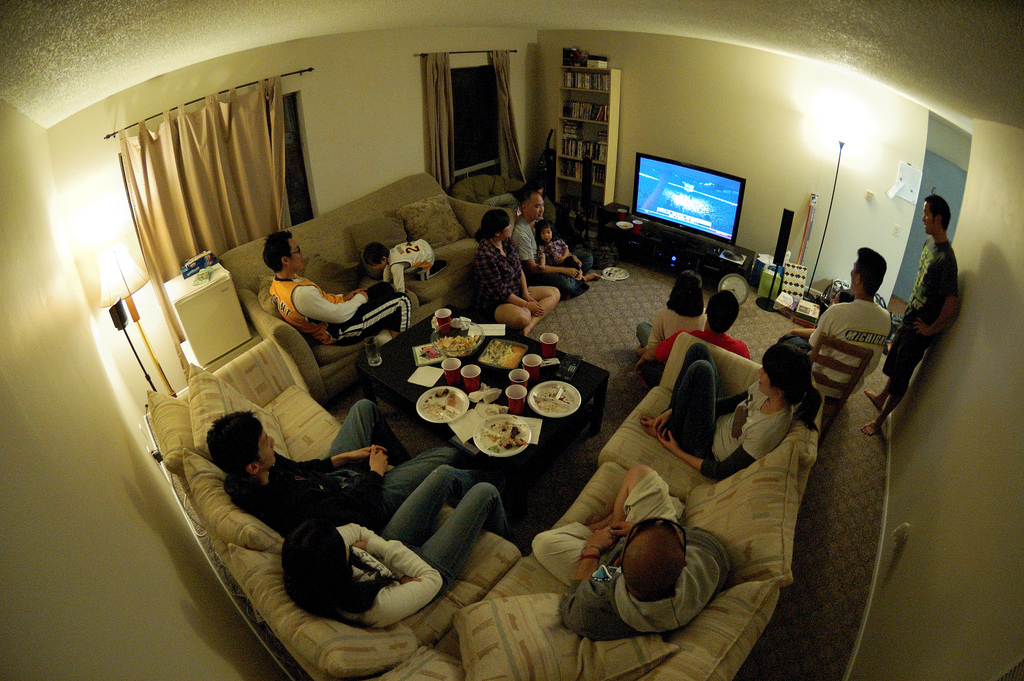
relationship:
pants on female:
[373, 456, 527, 591] [280, 465, 513, 629]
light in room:
[47, 160, 153, 340] [15, 26, 1020, 662]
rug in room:
[289, 232, 903, 678] [15, 26, 1020, 662]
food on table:
[477, 329, 527, 377] [349, 299, 617, 529]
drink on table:
[496, 374, 527, 413] [349, 299, 617, 529]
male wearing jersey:
[248, 228, 423, 365] [261, 260, 348, 345]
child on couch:
[360, 234, 434, 287] [205, 167, 501, 388]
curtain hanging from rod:
[112, 85, 285, 273] [105, 61, 315, 144]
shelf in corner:
[553, 55, 616, 213] [510, 24, 560, 195]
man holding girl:
[510, 180, 545, 289] [541, 217, 574, 263]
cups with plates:
[415, 338, 582, 444] [409, 333, 587, 446]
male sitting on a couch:
[204, 389, 393, 500] [139, 327, 516, 645]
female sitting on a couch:
[282, 463, 499, 630] [139, 327, 516, 645]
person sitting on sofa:
[635, 284, 847, 529] [622, 290, 864, 625]